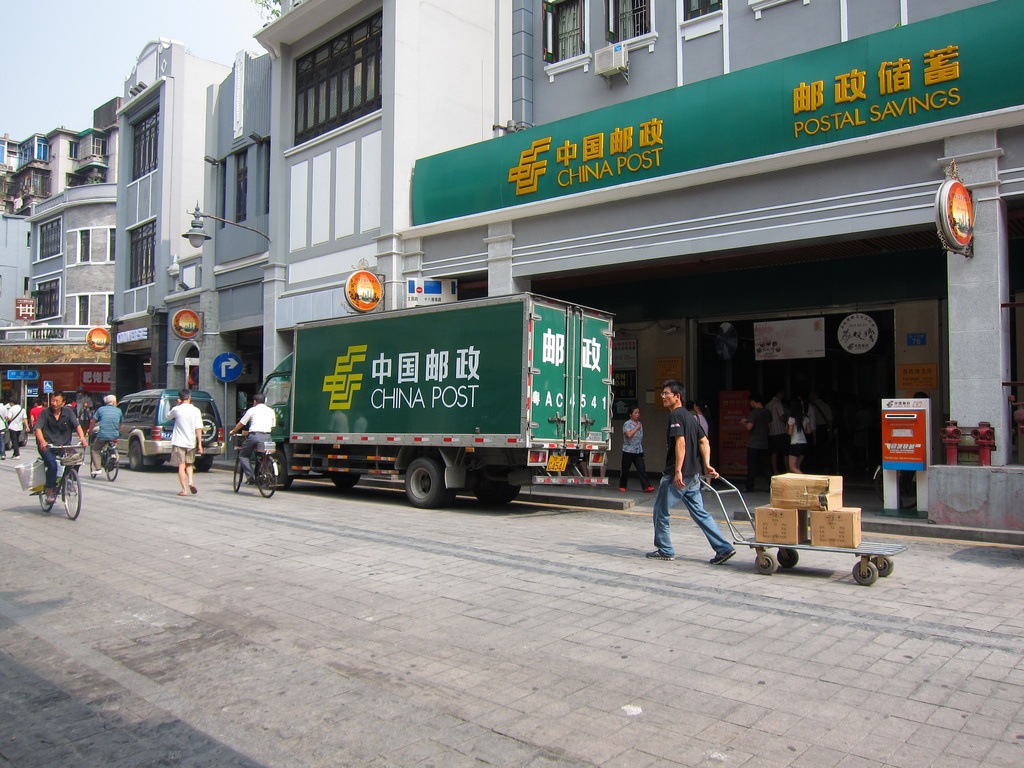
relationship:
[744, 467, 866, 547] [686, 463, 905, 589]
boxes stacked on a cart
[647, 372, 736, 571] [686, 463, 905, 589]
man pulling cart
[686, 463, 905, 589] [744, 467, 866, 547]
cart with boxes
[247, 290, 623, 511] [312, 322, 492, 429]
truck with graphics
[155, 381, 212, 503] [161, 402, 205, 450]
person walking away with t-shirt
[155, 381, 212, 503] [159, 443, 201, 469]
person walking away with shorts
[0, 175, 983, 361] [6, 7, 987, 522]
signs attached to buildings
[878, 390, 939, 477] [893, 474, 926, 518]
box on a post